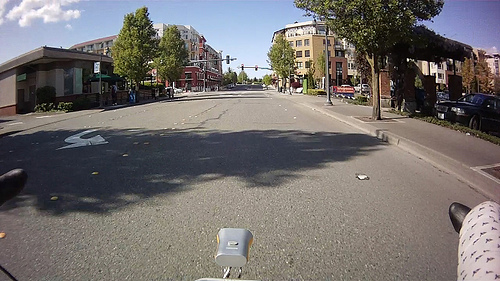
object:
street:
[0, 90, 494, 277]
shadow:
[1, 127, 392, 212]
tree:
[111, 4, 164, 103]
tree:
[155, 23, 191, 87]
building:
[284, 32, 337, 86]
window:
[304, 39, 314, 46]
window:
[295, 50, 304, 58]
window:
[294, 39, 303, 46]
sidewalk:
[285, 91, 499, 201]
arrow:
[56, 125, 109, 151]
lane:
[0, 94, 232, 233]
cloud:
[0, 0, 86, 31]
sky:
[2, 0, 499, 76]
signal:
[241, 62, 244, 71]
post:
[236, 65, 274, 71]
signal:
[253, 64, 260, 71]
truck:
[434, 91, 500, 133]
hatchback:
[354, 82, 371, 95]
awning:
[94, 72, 112, 80]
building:
[0, 44, 131, 115]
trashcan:
[129, 89, 138, 105]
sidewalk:
[0, 94, 190, 135]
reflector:
[51, 195, 59, 201]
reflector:
[91, 169, 100, 176]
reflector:
[159, 132, 165, 138]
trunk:
[369, 55, 383, 120]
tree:
[291, 0, 445, 121]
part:
[470, 160, 500, 182]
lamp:
[321, 21, 333, 109]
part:
[328, 104, 373, 117]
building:
[162, 20, 223, 90]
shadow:
[171, 95, 267, 101]